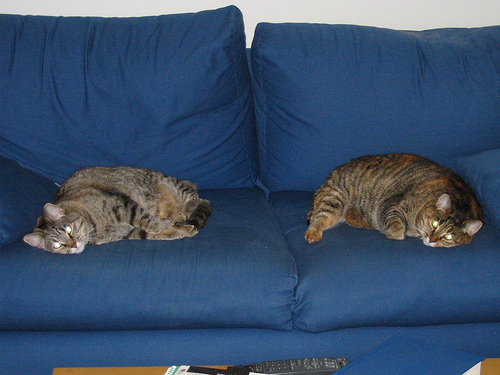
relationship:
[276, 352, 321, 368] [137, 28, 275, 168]
remote on couch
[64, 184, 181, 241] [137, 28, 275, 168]
cat on couch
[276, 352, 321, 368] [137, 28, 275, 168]
remote near couch